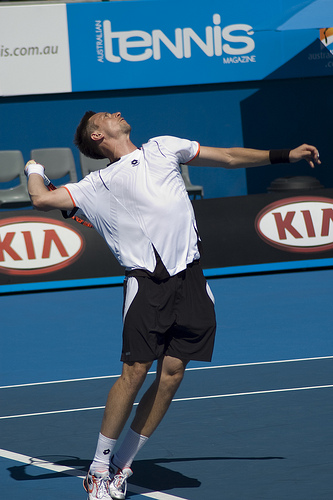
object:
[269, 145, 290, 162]
wristband